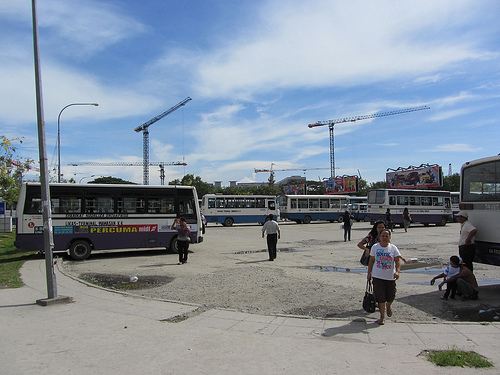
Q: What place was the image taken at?
A: It was taken at the sidewalk.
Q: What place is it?
A: It is a sidewalk.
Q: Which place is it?
A: It is a sidewalk.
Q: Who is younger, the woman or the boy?
A: The boy is younger than the woman.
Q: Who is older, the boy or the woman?
A: The woman is older than the boy.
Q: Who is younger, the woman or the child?
A: The child is younger than the woman.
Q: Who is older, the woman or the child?
A: The woman is older than the child.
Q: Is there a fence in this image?
A: No, there are no fences.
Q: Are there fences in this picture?
A: No, there are no fences.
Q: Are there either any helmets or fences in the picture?
A: No, there are no fences or helmets.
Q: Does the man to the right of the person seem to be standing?
A: Yes, the man is standing.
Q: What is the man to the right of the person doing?
A: The man is standing.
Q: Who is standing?
A: The man is standing.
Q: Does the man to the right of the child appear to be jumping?
A: No, the man is standing.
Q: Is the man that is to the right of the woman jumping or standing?
A: The man is standing.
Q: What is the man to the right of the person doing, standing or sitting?
A: The man is standing.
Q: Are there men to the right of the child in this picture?
A: Yes, there is a man to the right of the child.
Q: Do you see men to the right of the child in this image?
A: Yes, there is a man to the right of the child.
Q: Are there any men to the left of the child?
A: No, the man is to the right of the child.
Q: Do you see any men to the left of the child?
A: No, the man is to the right of the child.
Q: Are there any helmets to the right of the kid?
A: No, there is a man to the right of the kid.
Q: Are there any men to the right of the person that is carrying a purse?
A: Yes, there is a man to the right of the person.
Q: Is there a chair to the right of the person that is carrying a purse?
A: No, there is a man to the right of the person.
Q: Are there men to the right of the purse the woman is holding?
A: Yes, there is a man to the right of the purse.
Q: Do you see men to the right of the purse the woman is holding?
A: Yes, there is a man to the right of the purse.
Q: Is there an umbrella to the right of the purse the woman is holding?
A: No, there is a man to the right of the purse.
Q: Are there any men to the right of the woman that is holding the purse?
A: Yes, there is a man to the right of the woman.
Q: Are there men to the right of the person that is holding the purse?
A: Yes, there is a man to the right of the woman.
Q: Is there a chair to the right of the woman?
A: No, there is a man to the right of the woman.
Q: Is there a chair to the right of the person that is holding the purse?
A: No, there is a man to the right of the woman.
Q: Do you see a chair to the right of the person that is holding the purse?
A: No, there is a man to the right of the woman.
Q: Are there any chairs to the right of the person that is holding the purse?
A: No, there is a man to the right of the woman.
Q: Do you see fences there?
A: No, there are no fences.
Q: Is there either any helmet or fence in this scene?
A: No, there are no fences or helmets.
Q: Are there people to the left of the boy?
A: Yes, there is a person to the left of the boy.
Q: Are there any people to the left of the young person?
A: Yes, there is a person to the left of the boy.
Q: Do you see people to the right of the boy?
A: No, the person is to the left of the boy.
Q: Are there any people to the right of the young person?
A: No, the person is to the left of the boy.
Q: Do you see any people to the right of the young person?
A: No, the person is to the left of the boy.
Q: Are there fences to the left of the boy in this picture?
A: No, there is a person to the left of the boy.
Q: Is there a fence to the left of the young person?
A: No, there is a person to the left of the boy.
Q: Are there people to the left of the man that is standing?
A: Yes, there is a person to the left of the man.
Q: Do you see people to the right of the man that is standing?
A: No, the person is to the left of the man.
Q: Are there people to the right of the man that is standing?
A: No, the person is to the left of the man.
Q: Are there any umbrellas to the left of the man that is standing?
A: No, there is a person to the left of the man.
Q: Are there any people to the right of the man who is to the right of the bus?
A: Yes, there is a person to the right of the man.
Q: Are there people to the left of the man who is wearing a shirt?
A: No, the person is to the right of the man.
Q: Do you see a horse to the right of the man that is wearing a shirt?
A: No, there is a person to the right of the man.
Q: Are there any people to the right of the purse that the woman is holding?
A: Yes, there is a person to the right of the purse.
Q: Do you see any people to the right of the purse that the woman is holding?
A: Yes, there is a person to the right of the purse.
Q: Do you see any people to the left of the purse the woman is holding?
A: No, the person is to the right of the purse.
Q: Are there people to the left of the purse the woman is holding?
A: No, the person is to the right of the purse.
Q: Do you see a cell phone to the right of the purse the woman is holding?
A: No, there is a person to the right of the purse.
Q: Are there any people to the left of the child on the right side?
A: Yes, there is a person to the left of the child.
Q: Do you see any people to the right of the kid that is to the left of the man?
A: No, the person is to the left of the kid.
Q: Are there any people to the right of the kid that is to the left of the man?
A: No, the person is to the left of the kid.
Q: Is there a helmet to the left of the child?
A: No, there is a person to the left of the child.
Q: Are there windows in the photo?
A: Yes, there is a window.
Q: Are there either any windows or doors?
A: Yes, there is a window.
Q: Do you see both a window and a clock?
A: No, there is a window but no clocks.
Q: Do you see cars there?
A: No, there are no cars.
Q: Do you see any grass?
A: Yes, there is grass.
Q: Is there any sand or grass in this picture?
A: Yes, there is grass.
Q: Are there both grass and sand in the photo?
A: No, there is grass but no sand.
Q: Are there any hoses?
A: No, there are no hoses.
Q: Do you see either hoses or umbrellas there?
A: No, there are no hoses or umbrellas.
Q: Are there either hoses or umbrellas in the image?
A: No, there are no hoses or umbrellas.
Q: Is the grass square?
A: Yes, the grass is square.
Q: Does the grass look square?
A: Yes, the grass is square.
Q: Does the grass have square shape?
A: Yes, the grass is square.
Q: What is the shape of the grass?
A: The grass is square.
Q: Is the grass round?
A: No, the grass is square.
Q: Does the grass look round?
A: No, the grass is square.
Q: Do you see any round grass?
A: No, there is grass but it is square.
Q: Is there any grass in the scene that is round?
A: No, there is grass but it is square.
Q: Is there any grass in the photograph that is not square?
A: No, there is grass but it is square.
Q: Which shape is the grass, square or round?
A: The grass is square.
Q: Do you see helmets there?
A: No, there are no helmets.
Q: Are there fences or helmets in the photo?
A: No, there are no helmets or fences.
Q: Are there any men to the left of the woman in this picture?
A: Yes, there is a man to the left of the woman.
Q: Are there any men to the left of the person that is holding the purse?
A: Yes, there is a man to the left of the woman.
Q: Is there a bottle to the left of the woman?
A: No, there is a man to the left of the woman.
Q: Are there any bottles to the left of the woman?
A: No, there is a man to the left of the woman.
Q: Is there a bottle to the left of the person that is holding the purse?
A: No, there is a man to the left of the woman.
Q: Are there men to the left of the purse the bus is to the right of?
A: Yes, there is a man to the left of the purse.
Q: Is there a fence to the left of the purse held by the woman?
A: No, there is a man to the left of the purse.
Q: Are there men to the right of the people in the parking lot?
A: Yes, there is a man to the right of the people.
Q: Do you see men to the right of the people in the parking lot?
A: Yes, there is a man to the right of the people.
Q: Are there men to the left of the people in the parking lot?
A: No, the man is to the right of the people.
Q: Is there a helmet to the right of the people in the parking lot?
A: No, there is a man to the right of the people.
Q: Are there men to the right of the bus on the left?
A: Yes, there is a man to the right of the bus.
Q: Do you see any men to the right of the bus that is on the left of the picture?
A: Yes, there is a man to the right of the bus.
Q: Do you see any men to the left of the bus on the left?
A: No, the man is to the right of the bus.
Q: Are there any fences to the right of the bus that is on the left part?
A: No, there is a man to the right of the bus.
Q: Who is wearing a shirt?
A: The man is wearing a shirt.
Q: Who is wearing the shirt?
A: The man is wearing a shirt.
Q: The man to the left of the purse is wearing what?
A: The man is wearing a shirt.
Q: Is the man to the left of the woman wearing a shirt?
A: Yes, the man is wearing a shirt.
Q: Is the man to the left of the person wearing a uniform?
A: No, the man is wearing a shirt.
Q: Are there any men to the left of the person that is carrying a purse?
A: Yes, there is a man to the left of the person.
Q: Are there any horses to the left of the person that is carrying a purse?
A: No, there is a man to the left of the person.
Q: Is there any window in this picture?
A: Yes, there is a window.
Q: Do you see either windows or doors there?
A: Yes, there is a window.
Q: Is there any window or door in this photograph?
A: Yes, there is a window.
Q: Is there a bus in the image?
A: Yes, there is a bus.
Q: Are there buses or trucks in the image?
A: Yes, there is a bus.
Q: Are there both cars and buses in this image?
A: No, there is a bus but no cars.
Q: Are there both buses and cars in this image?
A: No, there is a bus but no cars.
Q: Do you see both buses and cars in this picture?
A: No, there is a bus but no cars.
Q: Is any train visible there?
A: No, there are no trains.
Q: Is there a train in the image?
A: No, there are no trains.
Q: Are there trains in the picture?
A: No, there are no trains.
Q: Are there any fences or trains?
A: No, there are no trains or fences.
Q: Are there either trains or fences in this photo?
A: No, there are no trains or fences.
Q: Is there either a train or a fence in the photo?
A: No, there are no trains or fences.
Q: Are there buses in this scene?
A: Yes, there is a bus.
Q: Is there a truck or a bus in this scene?
A: Yes, there is a bus.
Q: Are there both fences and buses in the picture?
A: No, there is a bus but no fences.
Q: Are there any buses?
A: Yes, there is a bus.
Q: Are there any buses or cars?
A: Yes, there is a bus.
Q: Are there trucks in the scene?
A: No, there are no trucks.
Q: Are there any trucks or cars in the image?
A: No, there are no trucks or cars.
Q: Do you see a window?
A: Yes, there is a window.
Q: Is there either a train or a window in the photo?
A: Yes, there is a window.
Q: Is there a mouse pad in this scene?
A: No, there are no mouse pads.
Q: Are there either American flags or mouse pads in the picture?
A: No, there are no mouse pads or American flags.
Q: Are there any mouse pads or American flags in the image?
A: No, there are no mouse pads or American flags.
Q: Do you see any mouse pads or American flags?
A: No, there are no mouse pads or American flags.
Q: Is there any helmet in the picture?
A: No, there are no helmets.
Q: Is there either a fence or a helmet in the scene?
A: No, there are no helmets or fences.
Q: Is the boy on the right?
A: Yes, the boy is on the right of the image.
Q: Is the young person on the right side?
A: Yes, the boy is on the right of the image.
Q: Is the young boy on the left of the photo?
A: No, the boy is on the right of the image.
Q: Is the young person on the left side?
A: No, the boy is on the right of the image.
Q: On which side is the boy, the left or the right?
A: The boy is on the right of the image.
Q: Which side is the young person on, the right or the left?
A: The boy is on the right of the image.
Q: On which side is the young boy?
A: The boy is on the right of the image.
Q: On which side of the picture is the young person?
A: The boy is on the right of the image.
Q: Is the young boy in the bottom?
A: Yes, the boy is in the bottom of the image.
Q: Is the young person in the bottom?
A: Yes, the boy is in the bottom of the image.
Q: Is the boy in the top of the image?
A: No, the boy is in the bottom of the image.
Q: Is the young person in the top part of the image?
A: No, the boy is in the bottom of the image.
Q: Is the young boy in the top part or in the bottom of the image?
A: The boy is in the bottom of the image.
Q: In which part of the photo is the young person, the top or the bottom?
A: The boy is in the bottom of the image.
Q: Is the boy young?
A: Yes, the boy is young.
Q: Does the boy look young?
A: Yes, the boy is young.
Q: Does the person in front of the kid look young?
A: Yes, the boy is young.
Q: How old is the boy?
A: The boy is young.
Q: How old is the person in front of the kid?
A: The boy is young.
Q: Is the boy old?
A: No, the boy is young.